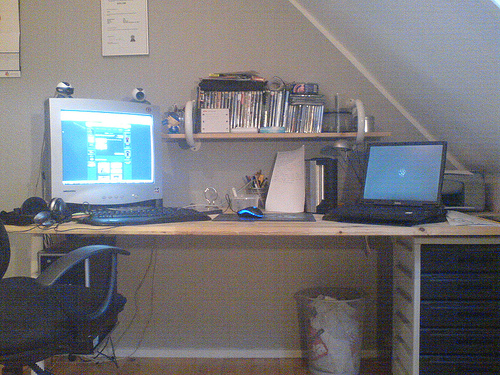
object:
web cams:
[129, 87, 154, 105]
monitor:
[46, 96, 164, 206]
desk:
[0, 199, 499, 374]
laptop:
[321, 138, 448, 228]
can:
[293, 286, 364, 375]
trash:
[309, 293, 339, 301]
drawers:
[423, 244, 500, 275]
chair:
[0, 217, 135, 374]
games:
[195, 91, 203, 134]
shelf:
[164, 86, 390, 143]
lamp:
[330, 137, 350, 153]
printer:
[440, 169, 490, 214]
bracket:
[181, 97, 196, 152]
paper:
[263, 144, 311, 214]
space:
[0, 0, 499, 375]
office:
[0, 0, 500, 375]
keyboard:
[82, 203, 213, 227]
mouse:
[236, 206, 265, 220]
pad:
[209, 208, 317, 223]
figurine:
[162, 102, 183, 133]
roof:
[285, 0, 500, 176]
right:
[286, 1, 499, 368]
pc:
[47, 95, 213, 226]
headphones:
[32, 197, 75, 232]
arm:
[35, 242, 130, 321]